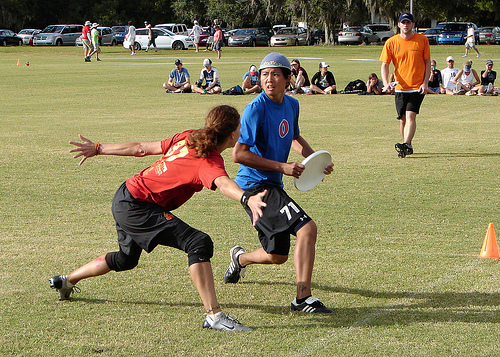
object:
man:
[223, 52, 333, 313]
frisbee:
[293, 151, 333, 193]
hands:
[281, 161, 333, 183]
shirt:
[235, 89, 299, 191]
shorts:
[242, 184, 311, 255]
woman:
[48, 104, 267, 332]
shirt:
[125, 130, 228, 211]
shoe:
[291, 297, 334, 314]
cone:
[479, 223, 499, 259]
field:
[0, 43, 499, 355]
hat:
[258, 52, 293, 70]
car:
[123, 27, 194, 50]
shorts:
[111, 181, 182, 255]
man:
[379, 12, 431, 156]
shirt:
[378, 33, 430, 91]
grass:
[0, 43, 499, 356]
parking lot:
[1, 21, 500, 49]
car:
[228, 27, 269, 45]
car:
[270, 27, 311, 46]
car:
[337, 25, 381, 46]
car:
[33, 24, 83, 44]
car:
[479, 27, 499, 44]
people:
[48, 104, 269, 334]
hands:
[69, 134, 267, 224]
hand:
[244, 189, 268, 227]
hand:
[70, 134, 95, 166]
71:
[278, 202, 301, 220]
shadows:
[59, 151, 499, 328]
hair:
[186, 105, 242, 160]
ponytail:
[185, 125, 220, 161]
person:
[162, 59, 191, 93]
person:
[192, 58, 221, 96]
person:
[310, 62, 335, 96]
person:
[480, 60, 495, 95]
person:
[453, 60, 481, 96]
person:
[85, 21, 107, 61]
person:
[80, 20, 95, 60]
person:
[124, 22, 137, 57]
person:
[142, 20, 159, 51]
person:
[186, 20, 207, 53]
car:
[436, 22, 479, 46]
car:
[364, 24, 394, 43]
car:
[154, 23, 189, 37]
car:
[111, 26, 127, 43]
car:
[1, 29, 25, 47]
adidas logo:
[300, 304, 317, 313]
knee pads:
[179, 227, 214, 259]